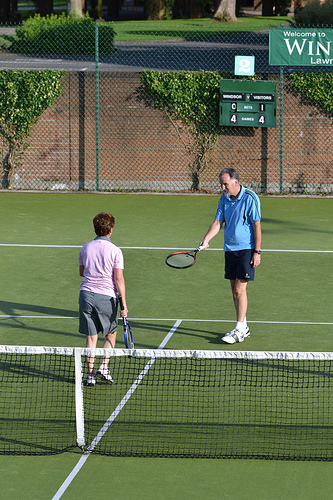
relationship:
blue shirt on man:
[215, 188, 263, 250] [198, 168, 262, 345]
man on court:
[198, 168, 262, 345] [76, 181, 184, 315]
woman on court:
[67, 212, 141, 328] [76, 181, 184, 315]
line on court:
[165, 308, 201, 374] [76, 181, 184, 315]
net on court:
[154, 345, 266, 457] [76, 181, 184, 315]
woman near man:
[67, 212, 141, 328] [198, 168, 262, 345]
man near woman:
[198, 168, 262, 345] [67, 212, 141, 328]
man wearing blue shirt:
[198, 168, 262, 345] [215, 188, 263, 250]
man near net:
[198, 168, 262, 345] [154, 345, 266, 457]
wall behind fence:
[112, 100, 170, 168] [128, 156, 205, 192]